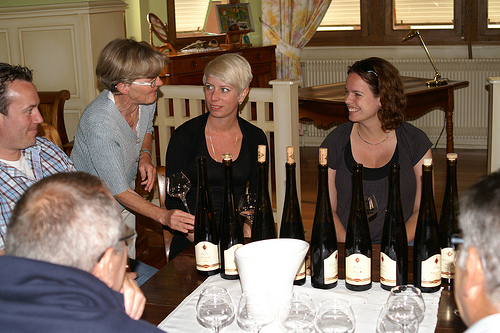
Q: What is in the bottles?
A: Wine.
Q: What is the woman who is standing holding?
A: A wine glass.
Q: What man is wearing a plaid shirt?
A: The one on the left.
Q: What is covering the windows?
A: Blinds.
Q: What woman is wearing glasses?
A: The one that is standing.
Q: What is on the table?
A: Wine glasses.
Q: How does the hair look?
A: Thinning gray.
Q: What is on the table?
A: Multiple bottles of wine.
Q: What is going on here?
A: A wine tasting scene.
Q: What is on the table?
A: Bottles of wine.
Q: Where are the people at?
A: Around the table.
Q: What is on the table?
A: Wine glasses.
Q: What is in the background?
A: Windows.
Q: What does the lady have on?
A: Black shirt.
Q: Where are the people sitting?
A: At the table.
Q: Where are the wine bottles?
A: On the table.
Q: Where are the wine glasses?
A: On the table.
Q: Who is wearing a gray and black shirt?
A: The woman on the right.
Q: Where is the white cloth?
A: On the table.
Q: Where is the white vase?
A: On the table.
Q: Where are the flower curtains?
A: On the window.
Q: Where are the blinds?
A: On the windows.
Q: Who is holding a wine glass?
A: The standing woman.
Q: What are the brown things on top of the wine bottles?
A: Corks.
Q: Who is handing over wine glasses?
A: Elderly lady.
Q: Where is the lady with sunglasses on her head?
A: Right grey shirt.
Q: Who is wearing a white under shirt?
A: Man left.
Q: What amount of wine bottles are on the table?
A: Nine.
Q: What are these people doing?
A: Wine tasting.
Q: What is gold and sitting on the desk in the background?
A: Table lamp.